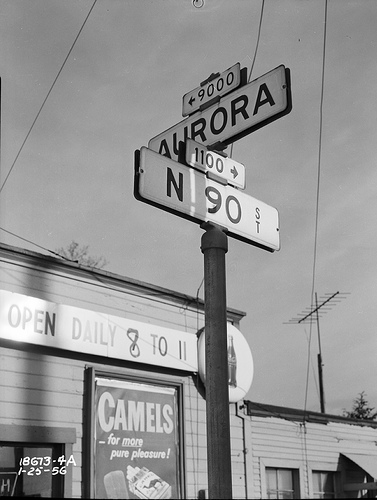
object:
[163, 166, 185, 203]
letter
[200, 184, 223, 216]
letter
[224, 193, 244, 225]
letter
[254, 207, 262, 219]
letter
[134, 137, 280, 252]
sign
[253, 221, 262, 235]
letter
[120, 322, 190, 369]
hours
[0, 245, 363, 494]
store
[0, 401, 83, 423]
siding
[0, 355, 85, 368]
siding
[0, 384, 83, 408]
siding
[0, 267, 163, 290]
siding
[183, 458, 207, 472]
siding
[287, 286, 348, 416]
antenna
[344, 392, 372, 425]
tree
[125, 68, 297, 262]
sign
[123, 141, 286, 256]
sign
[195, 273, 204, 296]
pole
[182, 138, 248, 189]
signs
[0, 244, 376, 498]
building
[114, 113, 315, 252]
sign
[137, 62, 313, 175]
sign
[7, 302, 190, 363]
letters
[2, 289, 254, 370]
sign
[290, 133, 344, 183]
ground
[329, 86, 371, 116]
ground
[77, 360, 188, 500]
poster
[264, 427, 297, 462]
wall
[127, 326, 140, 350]
number 7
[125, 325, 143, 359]
number 8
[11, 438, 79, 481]
number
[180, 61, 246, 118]
street sign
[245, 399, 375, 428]
roof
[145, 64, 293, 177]
aurora street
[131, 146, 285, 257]
n 90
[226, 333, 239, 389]
cola bottle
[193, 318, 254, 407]
sign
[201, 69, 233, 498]
pole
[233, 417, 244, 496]
wall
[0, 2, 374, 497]
photo